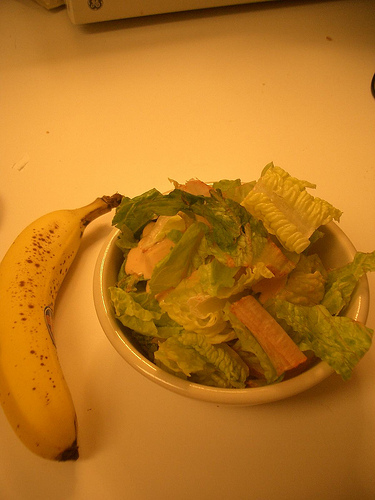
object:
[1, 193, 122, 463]
banana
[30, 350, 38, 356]
spot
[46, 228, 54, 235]
spot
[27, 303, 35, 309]
spot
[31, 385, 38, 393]
spot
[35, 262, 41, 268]
spot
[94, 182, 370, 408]
bowl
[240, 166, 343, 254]
lettuce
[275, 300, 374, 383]
lettuce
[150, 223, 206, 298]
lettuce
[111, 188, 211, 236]
lettuce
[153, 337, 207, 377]
lettuce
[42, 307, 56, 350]
sticker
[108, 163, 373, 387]
food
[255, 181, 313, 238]
rib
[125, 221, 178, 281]
salad dressing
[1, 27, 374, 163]
surface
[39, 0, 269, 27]
appliance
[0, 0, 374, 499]
surface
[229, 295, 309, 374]
lettuce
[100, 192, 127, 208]
tip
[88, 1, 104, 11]
logo